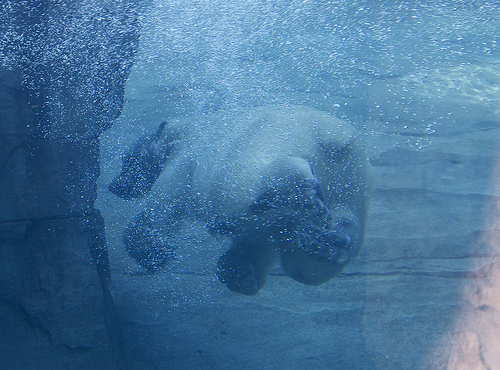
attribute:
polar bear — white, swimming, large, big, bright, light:
[101, 102, 377, 295]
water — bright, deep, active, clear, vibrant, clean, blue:
[2, 0, 497, 369]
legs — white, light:
[261, 158, 366, 269]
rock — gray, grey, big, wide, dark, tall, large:
[2, 2, 152, 369]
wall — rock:
[0, 3, 148, 370]